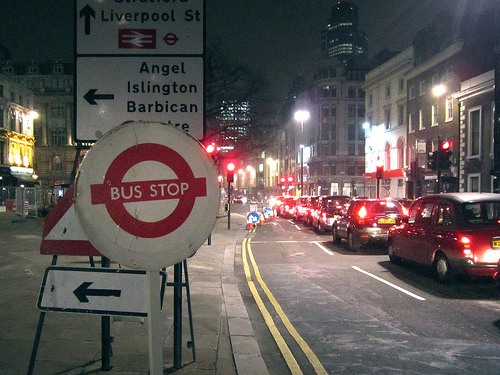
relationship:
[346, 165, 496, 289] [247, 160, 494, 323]
cars parked in a line on road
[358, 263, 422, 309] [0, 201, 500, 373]
line in road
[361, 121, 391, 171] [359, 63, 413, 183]
lights on building